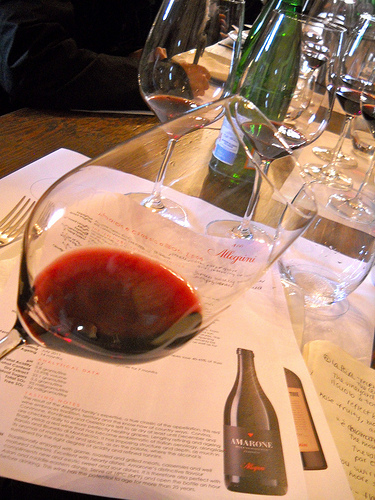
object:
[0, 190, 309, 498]
paper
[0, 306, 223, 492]
writing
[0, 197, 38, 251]
fork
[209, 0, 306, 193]
bottle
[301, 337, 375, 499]
paper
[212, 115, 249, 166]
label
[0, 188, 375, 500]
information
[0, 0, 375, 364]
glasses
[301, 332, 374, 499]
notes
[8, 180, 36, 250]
bottle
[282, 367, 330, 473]
bottle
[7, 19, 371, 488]
table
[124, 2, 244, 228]
glasses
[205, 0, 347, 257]
glasses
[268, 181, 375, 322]
glasses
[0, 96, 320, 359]
glasses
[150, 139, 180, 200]
stems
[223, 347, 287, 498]
bottle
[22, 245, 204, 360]
wine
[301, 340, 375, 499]
page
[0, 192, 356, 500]
page